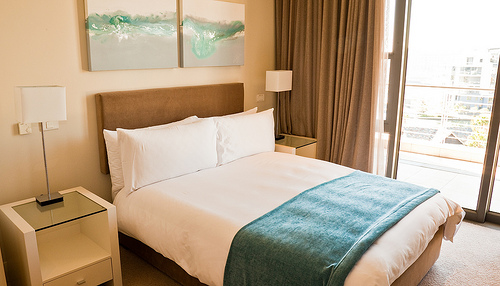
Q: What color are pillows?
A: White.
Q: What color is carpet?
A: Gray.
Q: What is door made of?
A: Glass.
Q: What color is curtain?
A: Brown.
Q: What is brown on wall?
A: Head board.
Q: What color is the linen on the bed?
A: White.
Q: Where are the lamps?
A: On nightstands.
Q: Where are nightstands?
A: Next to the bed.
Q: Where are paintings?
A: On the wall.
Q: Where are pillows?
A: On the bed.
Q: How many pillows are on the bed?
A: Four.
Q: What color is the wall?
A: Beige.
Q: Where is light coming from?
A: Glass doors.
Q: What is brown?
A: Headboard.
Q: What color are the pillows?
A: White.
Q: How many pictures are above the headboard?
A: Two.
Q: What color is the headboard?
A: Brown.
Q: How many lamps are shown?
A: Two.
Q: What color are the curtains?
A: Brown.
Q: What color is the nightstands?
A: White.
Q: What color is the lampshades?
A: White.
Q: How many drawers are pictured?
A: One.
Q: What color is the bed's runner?
A: Teal.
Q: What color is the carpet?
A: Brown.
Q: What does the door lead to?
A: Patio.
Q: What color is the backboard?
A: Brown.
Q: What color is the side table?
A: White.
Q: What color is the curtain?
A: Beige.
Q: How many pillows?
A: Four.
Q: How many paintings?
A: Two.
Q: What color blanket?
A: Teal.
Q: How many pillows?
A: Four.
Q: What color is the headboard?
A: Brown.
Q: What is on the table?
A: Lamp.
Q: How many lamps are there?
A: Two.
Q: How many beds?
A: 1.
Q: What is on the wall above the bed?
A: Painting.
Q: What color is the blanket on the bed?
A: Green.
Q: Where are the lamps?
A: On the night stands.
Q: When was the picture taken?
A: During daytime.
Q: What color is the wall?
A: Light brown.